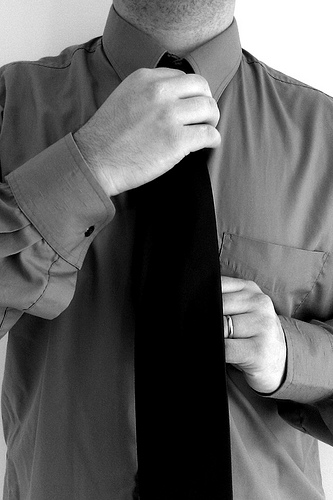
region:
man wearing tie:
[65, 67, 311, 433]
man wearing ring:
[224, 313, 237, 336]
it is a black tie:
[132, 58, 235, 498]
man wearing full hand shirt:
[2, 51, 331, 450]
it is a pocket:
[219, 224, 329, 322]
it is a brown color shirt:
[3, 19, 332, 498]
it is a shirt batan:
[74, 214, 107, 253]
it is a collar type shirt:
[103, 6, 255, 92]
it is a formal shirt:
[3, 11, 331, 470]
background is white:
[250, 9, 311, 54]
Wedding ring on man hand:
[224, 313, 239, 336]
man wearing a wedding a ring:
[223, 309, 240, 329]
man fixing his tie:
[150, 58, 208, 157]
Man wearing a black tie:
[128, 265, 239, 478]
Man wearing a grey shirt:
[218, 93, 319, 300]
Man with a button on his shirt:
[76, 218, 99, 243]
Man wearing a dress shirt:
[210, 69, 296, 241]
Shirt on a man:
[23, 71, 96, 122]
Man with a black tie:
[142, 184, 236, 311]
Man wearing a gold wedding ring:
[222, 316, 237, 337]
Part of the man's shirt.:
[261, 125, 314, 179]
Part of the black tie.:
[137, 334, 201, 450]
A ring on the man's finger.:
[225, 315, 234, 338]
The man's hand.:
[75, 67, 224, 196]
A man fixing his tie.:
[0, 2, 329, 497]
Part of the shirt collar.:
[105, 19, 142, 68]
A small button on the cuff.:
[82, 223, 95, 237]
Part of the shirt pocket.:
[220, 230, 326, 316]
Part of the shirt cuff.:
[17, 167, 76, 212]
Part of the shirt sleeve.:
[13, 262, 36, 297]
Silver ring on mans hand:
[222, 309, 242, 340]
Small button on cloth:
[72, 219, 104, 250]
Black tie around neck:
[118, 40, 211, 369]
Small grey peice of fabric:
[5, 453, 45, 497]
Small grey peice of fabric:
[53, 446, 83, 497]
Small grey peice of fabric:
[84, 446, 110, 497]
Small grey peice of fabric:
[242, 453, 275, 495]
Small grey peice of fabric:
[272, 459, 307, 490]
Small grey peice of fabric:
[252, 245, 312, 265]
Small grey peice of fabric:
[75, 288, 128, 374]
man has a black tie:
[2, 5, 328, 498]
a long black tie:
[115, 51, 249, 499]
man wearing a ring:
[219, 273, 288, 392]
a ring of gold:
[221, 307, 240, 342]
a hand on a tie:
[64, 53, 242, 215]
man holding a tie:
[0, 1, 329, 493]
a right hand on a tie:
[2, 36, 223, 326]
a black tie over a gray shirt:
[0, 10, 329, 495]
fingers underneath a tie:
[124, 260, 310, 410]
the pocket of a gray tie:
[213, 187, 331, 290]